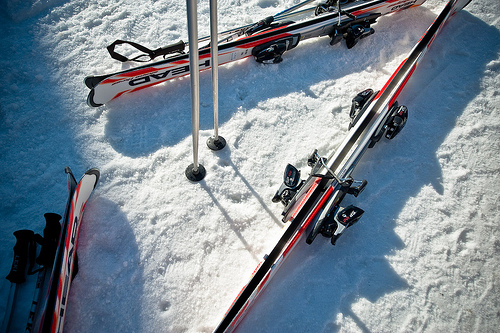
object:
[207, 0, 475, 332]
skating board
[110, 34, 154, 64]
band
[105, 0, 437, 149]
shadow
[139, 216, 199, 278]
footprint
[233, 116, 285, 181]
footprint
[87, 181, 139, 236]
footprint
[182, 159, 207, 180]
wheels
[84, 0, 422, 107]
board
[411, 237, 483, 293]
footprints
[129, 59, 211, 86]
label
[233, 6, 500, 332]
shadow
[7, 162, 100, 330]
skating gear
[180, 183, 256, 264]
shadow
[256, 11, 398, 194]
clock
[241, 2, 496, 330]
skishadow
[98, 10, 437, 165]
skishadow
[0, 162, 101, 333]
skis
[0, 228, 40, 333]
poles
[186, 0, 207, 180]
poles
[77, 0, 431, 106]
skis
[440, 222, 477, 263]
footprint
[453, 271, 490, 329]
footprint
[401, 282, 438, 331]
footprint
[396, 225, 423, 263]
footprint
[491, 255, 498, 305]
footprint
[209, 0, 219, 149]
pole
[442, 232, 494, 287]
ice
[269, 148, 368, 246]
ski brackets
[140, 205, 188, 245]
ice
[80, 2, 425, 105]
ski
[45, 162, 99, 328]
ski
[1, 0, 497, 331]
snow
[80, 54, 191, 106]
tail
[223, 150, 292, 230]
shadow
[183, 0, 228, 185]
skipoles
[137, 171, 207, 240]
sun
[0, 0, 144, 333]
shadow